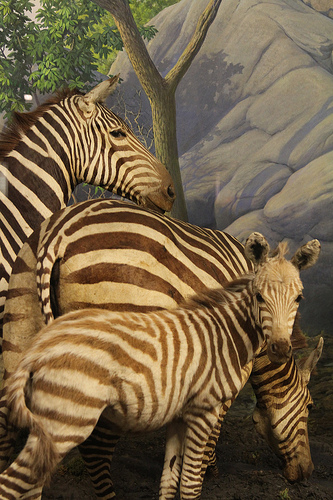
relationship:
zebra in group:
[9, 232, 319, 498] [3, 78, 327, 498]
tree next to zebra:
[5, 2, 227, 221] [0, 228, 318, 500]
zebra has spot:
[9, 232, 319, 498] [166, 450, 178, 472]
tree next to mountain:
[5, 2, 227, 221] [97, 0, 328, 288]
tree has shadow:
[5, 2, 227, 221] [112, 52, 236, 140]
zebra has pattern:
[9, 232, 319, 498] [78, 324, 145, 375]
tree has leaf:
[5, 2, 227, 221] [83, 12, 94, 20]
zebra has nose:
[0, 228, 318, 500] [145, 163, 173, 210]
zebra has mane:
[9, 232, 319, 498] [167, 279, 262, 307]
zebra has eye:
[9, 232, 319, 498] [256, 289, 267, 304]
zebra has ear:
[9, 232, 319, 498] [249, 231, 267, 256]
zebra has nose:
[9, 232, 319, 498] [145, 163, 173, 210]